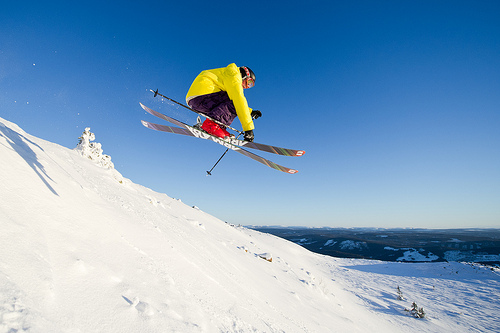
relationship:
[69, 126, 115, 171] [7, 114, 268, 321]
tree top of slope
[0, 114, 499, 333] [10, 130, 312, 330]
snow on slope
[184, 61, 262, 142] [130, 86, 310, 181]
man on skis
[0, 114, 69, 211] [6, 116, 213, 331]
shadow on snow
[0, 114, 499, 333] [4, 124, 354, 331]
snow on slope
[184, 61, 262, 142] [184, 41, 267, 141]
man wearing jacket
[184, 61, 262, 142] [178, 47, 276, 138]
man wearing jacket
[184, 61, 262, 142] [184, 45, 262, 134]
man wearing jacket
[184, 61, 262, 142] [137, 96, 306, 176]
man on skiis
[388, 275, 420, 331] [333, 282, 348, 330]
tree growing out of snow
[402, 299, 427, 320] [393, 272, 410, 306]
tree growing out of snow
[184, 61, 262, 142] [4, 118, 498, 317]
man skiing on snow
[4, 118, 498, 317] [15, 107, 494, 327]
snow covering ground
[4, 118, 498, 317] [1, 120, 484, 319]
snow covering ground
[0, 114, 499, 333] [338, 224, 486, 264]
snow covering hill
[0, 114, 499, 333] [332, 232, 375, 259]
snow covering hill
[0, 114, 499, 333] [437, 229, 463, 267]
snow covering hill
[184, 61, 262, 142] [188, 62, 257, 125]
man wearing jacket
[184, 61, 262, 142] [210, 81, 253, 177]
man holding poles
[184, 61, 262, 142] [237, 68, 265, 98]
man wearing goggles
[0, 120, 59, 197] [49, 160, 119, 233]
shadow on top of snow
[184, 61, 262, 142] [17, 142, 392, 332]
man travelling down slope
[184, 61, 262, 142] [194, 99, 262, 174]
man holding poles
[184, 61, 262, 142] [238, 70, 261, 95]
man wearing goggles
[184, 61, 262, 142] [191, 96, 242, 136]
man wearing pants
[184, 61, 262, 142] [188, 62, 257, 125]
man with jacket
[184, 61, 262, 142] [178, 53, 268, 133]
man in jacket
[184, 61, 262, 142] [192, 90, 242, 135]
man in pants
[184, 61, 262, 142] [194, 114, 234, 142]
man in shoes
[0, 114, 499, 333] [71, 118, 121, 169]
snow covered tree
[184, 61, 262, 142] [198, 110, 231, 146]
man in shoes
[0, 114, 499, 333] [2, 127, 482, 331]
snow covered landscape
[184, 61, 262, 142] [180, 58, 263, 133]
man wearing jacket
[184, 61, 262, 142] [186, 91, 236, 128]
man wearing pants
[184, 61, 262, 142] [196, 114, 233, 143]
man wearing boots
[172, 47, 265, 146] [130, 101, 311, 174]
man on skis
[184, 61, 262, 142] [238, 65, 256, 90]
man wearing goggles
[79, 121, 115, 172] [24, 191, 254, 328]
tree growing snow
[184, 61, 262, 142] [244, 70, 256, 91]
man wearing goggles